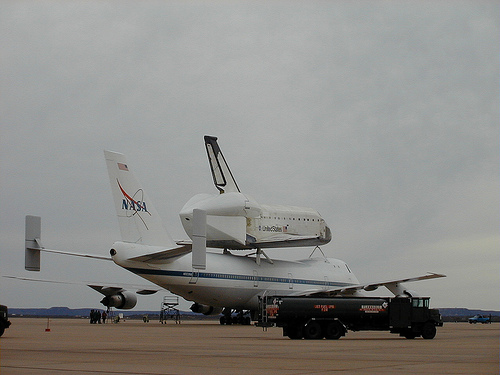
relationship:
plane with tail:
[177, 135, 333, 265] [202, 134, 241, 192]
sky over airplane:
[4, 3, 499, 312] [17, 149, 446, 324]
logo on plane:
[116, 178, 152, 231] [84, 133, 356, 260]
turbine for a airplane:
[102, 288, 135, 315] [17, 149, 446, 324]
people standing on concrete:
[143, 314, 146, 322] [58, 275, 438, 366]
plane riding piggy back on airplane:
[177, 135, 333, 265] [131, 230, 451, 338]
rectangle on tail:
[205, 140, 227, 188] [201, 134, 241, 193]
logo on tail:
[118, 170, 134, 227] [87, 137, 174, 247]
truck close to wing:
[277, 290, 453, 345] [287, 268, 454, 293]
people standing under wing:
[88, 305, 108, 322] [3, 272, 169, 310]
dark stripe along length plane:
[128, 266, 365, 286] [20, 128, 445, 323]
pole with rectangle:
[19, 209, 76, 301] [18, 206, 47, 275]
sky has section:
[4, 3, 499, 312] [58, 42, 148, 141]